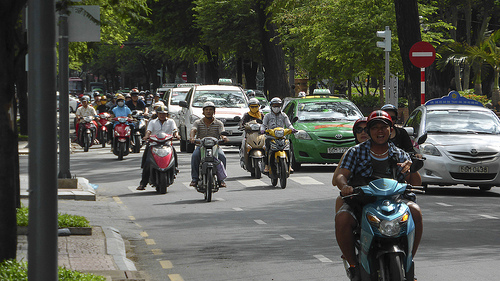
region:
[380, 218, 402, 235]
Clear headlight on front of moped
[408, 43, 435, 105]
Red and white street sign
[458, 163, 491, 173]
License plate on front of car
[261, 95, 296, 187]
Person riding yellow moped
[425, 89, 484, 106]
Blue sign on top of car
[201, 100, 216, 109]
White safety helmet on man's head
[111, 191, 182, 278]
Yellow caution line on side of street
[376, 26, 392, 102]
Tall metal traffic light on roadway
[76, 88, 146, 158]
Group of people riding mopeds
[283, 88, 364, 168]
Green taxie driving down roadway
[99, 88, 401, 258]
Motor cycles on road.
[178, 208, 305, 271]
Road is grey color.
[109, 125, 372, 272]
White and yellow lines in road.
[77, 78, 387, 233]
Two wheeler riders are wearing helmet.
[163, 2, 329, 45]
Leaves are green color.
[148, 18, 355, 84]
Trees on sides of the road.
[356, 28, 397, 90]
Traffic light is white color.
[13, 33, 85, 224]
Pole is grey color.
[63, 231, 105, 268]
Patheway is brown color.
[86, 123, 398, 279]
Shadow falls on road.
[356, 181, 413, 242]
motorcycle is bright aqua color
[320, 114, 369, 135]
orange on the hood of car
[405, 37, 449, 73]
red round street sign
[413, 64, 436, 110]
red and white stripes on the pole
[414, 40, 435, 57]
white line through red round sign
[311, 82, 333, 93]
sign on top of a taxi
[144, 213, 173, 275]
yellow lines on th street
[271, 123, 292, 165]
motorcycle is a mustard yellow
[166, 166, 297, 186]
pedistrian walkway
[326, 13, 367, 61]
trees next to the traffic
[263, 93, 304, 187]
biker on the road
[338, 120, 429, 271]
biker on the road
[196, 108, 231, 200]
biker on the road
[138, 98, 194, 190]
biker on the road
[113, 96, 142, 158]
biker on the road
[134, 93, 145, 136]
biker on the road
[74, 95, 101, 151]
biker on the road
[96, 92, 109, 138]
biker on the road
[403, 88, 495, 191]
car on side of road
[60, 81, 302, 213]
several people riding scooters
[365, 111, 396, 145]
a man with a red and black helmet on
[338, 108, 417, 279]
a man and woman riding a scooter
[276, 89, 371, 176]
a green car driving down the street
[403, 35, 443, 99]
a do not enter sign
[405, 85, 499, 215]
a white car driving down the street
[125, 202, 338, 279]
a city street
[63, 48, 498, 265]
a busy city street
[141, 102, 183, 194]
a man riding a silver and red scooter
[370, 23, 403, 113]
a white metal traffic light